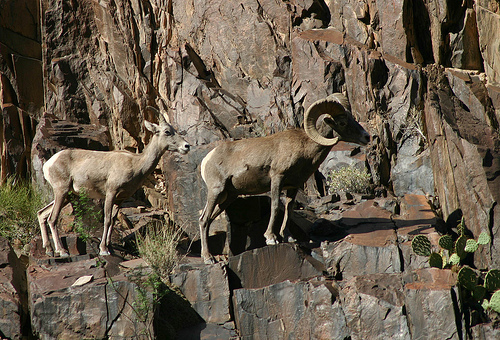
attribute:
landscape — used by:
[5, 1, 497, 338]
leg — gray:
[196, 191, 221, 266]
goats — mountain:
[28, 85, 367, 282]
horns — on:
[297, 93, 359, 168]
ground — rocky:
[6, 193, 459, 327]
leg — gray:
[261, 171, 283, 247]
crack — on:
[426, 81, 467, 214]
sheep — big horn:
[194, 77, 386, 252]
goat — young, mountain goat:
[179, 64, 409, 295]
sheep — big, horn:
[200, 92, 370, 264]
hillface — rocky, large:
[5, 3, 498, 338]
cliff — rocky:
[0, 0, 497, 337]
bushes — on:
[4, 179, 34, 239]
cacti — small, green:
[410, 202, 499, 313]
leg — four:
[105, 197, 120, 253]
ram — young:
[28, 92, 212, 269]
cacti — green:
[415, 236, 442, 262]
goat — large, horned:
[178, 79, 396, 285]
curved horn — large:
[300, 86, 352, 148]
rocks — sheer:
[266, 258, 403, 336]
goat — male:
[198, 92, 371, 262]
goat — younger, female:
[36, 105, 192, 259]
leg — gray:
[280, 188, 296, 245]